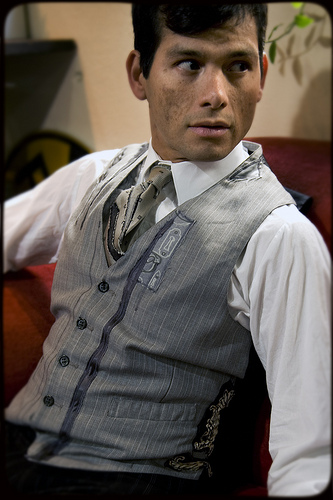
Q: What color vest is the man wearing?
A: Gray.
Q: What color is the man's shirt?
A: White.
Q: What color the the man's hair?
A: Black.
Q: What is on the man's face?
A: Freckles.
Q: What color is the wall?
A: Peach.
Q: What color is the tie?
A: Gray and black.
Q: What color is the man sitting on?
A: Red.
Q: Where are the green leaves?
A: Behind the man's head.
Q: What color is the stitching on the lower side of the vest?
A: Gold.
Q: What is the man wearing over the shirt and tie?
A: A vest.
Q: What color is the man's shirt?
A: White.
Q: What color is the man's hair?
A: Black.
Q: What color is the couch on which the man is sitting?
A: Red.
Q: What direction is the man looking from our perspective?
A: To the right.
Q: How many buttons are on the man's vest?
A: Four.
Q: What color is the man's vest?
A: Grey.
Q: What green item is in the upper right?
A: A plant.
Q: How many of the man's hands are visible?
A: None.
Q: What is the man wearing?
A: A vest and dress shirt.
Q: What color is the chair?
A: Red.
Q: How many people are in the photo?
A: One.